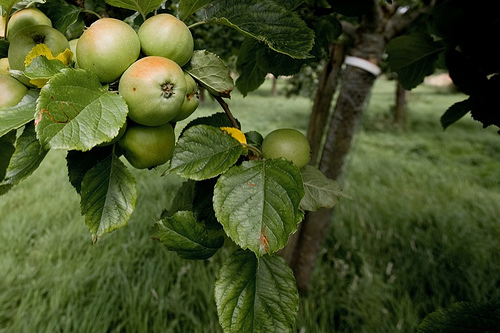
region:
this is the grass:
[364, 139, 467, 258]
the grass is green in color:
[363, 191, 472, 298]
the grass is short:
[372, 164, 464, 273]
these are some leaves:
[178, 150, 299, 330]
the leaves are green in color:
[228, 167, 282, 313]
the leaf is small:
[228, 168, 298, 251]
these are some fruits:
[94, 23, 182, 93]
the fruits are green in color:
[88, 29, 166, 69]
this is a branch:
[316, 59, 367, 144]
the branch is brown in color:
[318, 82, 350, 138]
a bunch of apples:
[8, 10, 325, 212]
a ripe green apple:
[97, 42, 197, 147]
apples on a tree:
[8, 10, 493, 315]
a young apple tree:
[5, 3, 498, 322]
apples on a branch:
[4, 3, 359, 220]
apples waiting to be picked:
[8, 7, 333, 222]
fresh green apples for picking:
[6, 0, 462, 213]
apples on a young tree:
[4, 1, 489, 321]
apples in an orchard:
[7, 7, 496, 331]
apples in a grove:
[10, 4, 489, 329]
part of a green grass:
[392, 227, 456, 307]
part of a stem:
[315, 99, 346, 191]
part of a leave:
[235, 275, 269, 317]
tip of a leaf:
[251, 252, 271, 269]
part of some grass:
[376, 257, 416, 329]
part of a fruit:
[156, 76, 178, 98]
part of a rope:
[348, 45, 385, 82]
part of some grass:
[381, 235, 421, 284]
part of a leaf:
[313, 175, 332, 227]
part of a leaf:
[99, 183, 123, 224]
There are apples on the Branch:
[3, 18, 329, 233]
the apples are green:
[4, 8, 239, 159]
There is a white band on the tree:
[343, 57, 389, 88]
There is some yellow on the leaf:
[186, 118, 264, 175]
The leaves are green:
[7, 3, 322, 325]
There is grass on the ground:
[3, 72, 498, 332]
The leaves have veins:
[183, 123, 300, 268]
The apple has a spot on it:
[114, 58, 185, 130]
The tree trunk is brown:
[305, 1, 400, 313]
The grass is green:
[1, 75, 499, 331]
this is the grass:
[385, 152, 473, 329]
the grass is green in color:
[392, 159, 485, 284]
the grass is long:
[380, 173, 479, 323]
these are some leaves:
[223, 173, 279, 330]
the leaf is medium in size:
[228, 167, 280, 256]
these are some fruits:
[101, 40, 185, 159]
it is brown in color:
[328, 116, 345, 172]